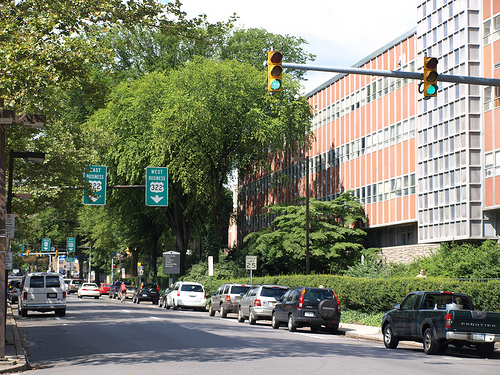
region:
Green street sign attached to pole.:
[138, 158, 197, 295]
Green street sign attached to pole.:
[56, 141, 110, 260]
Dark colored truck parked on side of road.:
[381, 280, 466, 366]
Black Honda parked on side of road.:
[273, 282, 333, 373]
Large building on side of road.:
[318, 117, 453, 245]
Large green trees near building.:
[182, 132, 324, 244]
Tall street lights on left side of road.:
[11, 124, 71, 255]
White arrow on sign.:
[145, 185, 185, 226]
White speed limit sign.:
[225, 250, 317, 301]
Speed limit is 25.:
[213, 246, 296, 336]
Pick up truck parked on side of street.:
[368, 281, 499, 362]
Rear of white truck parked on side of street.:
[11, 266, 71, 318]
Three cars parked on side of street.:
[208, 281, 345, 334]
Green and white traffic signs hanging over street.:
[78, 155, 180, 210]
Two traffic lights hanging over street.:
[258, 32, 498, 119]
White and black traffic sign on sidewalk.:
[238, 252, 266, 284]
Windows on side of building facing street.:
[268, 62, 413, 228]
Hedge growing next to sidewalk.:
[267, 272, 499, 325]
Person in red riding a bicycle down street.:
[116, 281, 131, 303]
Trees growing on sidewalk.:
[61, 9, 295, 299]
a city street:
[16, 17, 486, 368]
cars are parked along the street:
[128, 261, 494, 356]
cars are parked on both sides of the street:
[14, 247, 479, 367]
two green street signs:
[70, 151, 175, 212]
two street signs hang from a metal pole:
[82, 153, 192, 225]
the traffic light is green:
[257, 42, 498, 112]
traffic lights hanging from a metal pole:
[256, 28, 484, 120]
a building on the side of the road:
[221, 20, 498, 330]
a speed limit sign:
[243, 251, 265, 284]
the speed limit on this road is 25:
[244, 253, 262, 289]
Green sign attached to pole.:
[140, 150, 189, 225]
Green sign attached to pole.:
[73, 160, 128, 230]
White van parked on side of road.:
[18, 241, 88, 354]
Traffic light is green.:
[264, 65, 298, 108]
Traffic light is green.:
[417, 78, 441, 122]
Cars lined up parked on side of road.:
[175, 267, 462, 359]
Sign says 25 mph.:
[244, 253, 286, 310]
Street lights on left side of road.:
[13, 117, 59, 237]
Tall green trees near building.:
[91, 74, 266, 202]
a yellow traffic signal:
[265, 48, 290, 94]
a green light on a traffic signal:
[269, 77, 280, 90]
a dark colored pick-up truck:
[379, 282, 499, 356]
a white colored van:
[17, 268, 69, 317]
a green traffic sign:
[143, 164, 168, 208]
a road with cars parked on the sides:
[32, 287, 497, 372]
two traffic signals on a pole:
[251, 42, 498, 103]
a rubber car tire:
[379, 323, 401, 348]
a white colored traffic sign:
[243, 254, 260, 282]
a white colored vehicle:
[163, 278, 207, 308]